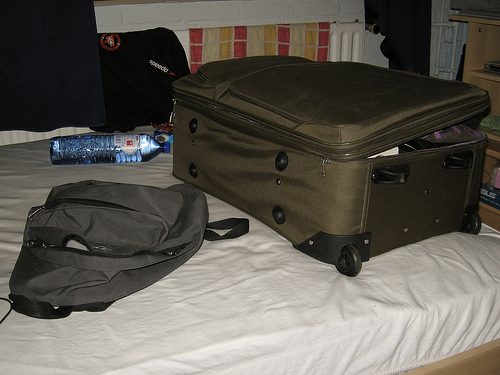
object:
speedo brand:
[148, 59, 169, 74]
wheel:
[460, 209, 481, 236]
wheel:
[336, 244, 363, 278]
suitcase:
[169, 56, 492, 277]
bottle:
[48, 134, 170, 165]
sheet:
[0, 124, 500, 375]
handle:
[9, 294, 72, 320]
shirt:
[87, 27, 192, 134]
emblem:
[99, 32, 123, 53]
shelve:
[443, 14, 500, 84]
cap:
[161, 140, 171, 154]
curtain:
[190, 24, 332, 72]